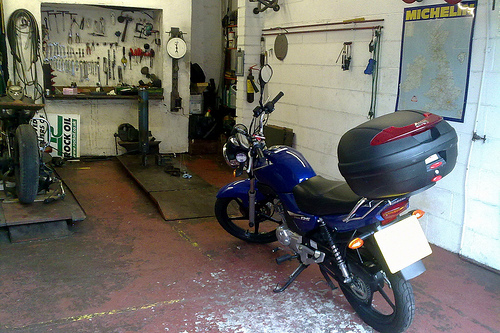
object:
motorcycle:
[215, 91, 459, 332]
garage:
[0, 0, 497, 333]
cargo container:
[335, 109, 459, 200]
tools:
[40, 3, 163, 98]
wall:
[0, 0, 187, 152]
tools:
[255, 18, 385, 120]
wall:
[262, 0, 395, 109]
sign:
[395, 1, 479, 124]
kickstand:
[269, 249, 312, 294]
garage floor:
[0, 153, 499, 331]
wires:
[5, 6, 41, 101]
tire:
[11, 123, 40, 207]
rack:
[0, 151, 87, 240]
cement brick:
[305, 85, 351, 111]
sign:
[33, 113, 80, 163]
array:
[41, 9, 156, 83]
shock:
[314, 219, 354, 285]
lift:
[116, 151, 215, 215]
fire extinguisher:
[245, 64, 258, 104]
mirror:
[259, 63, 274, 83]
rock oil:
[60, 115, 74, 159]